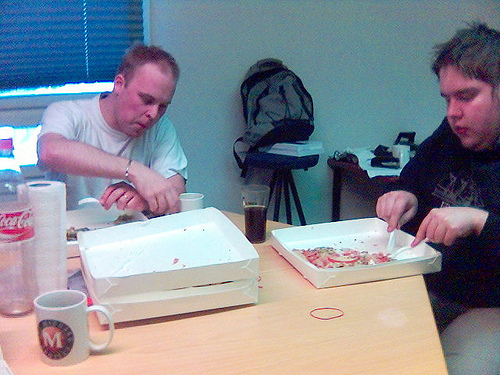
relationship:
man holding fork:
[31, 40, 186, 252] [79, 190, 134, 212]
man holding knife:
[384, 16, 499, 366] [379, 215, 396, 256]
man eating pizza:
[376, 21, 500, 337] [266, 212, 413, 289]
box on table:
[268, 213, 445, 290] [130, 323, 432, 373]